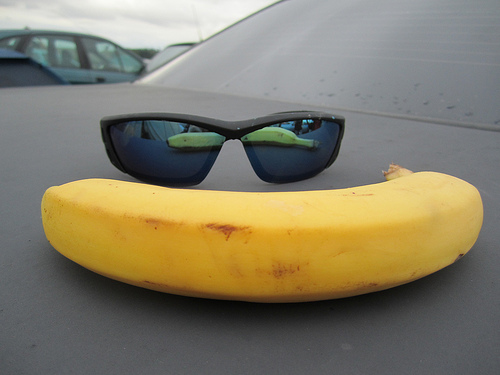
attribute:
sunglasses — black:
[97, 108, 347, 189]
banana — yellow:
[34, 160, 486, 307]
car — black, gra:
[1, 1, 499, 375]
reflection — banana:
[166, 128, 319, 154]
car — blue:
[1, 27, 149, 86]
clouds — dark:
[1, 0, 280, 52]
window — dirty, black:
[129, 2, 499, 136]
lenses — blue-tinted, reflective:
[105, 118, 342, 187]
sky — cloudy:
[0, 1, 275, 52]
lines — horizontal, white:
[200, 0, 496, 69]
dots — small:
[219, 75, 499, 129]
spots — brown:
[140, 215, 379, 300]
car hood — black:
[2, 79, 499, 374]